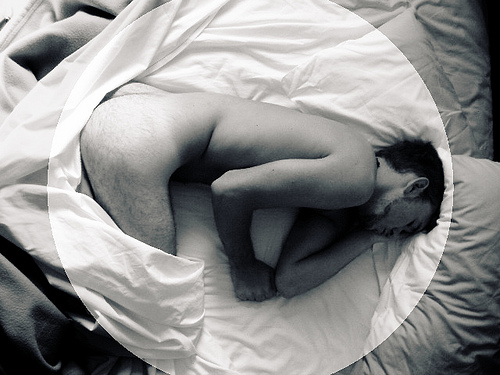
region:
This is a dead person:
[58, 53, 485, 337]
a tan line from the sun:
[131, 92, 191, 167]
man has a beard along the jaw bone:
[360, 193, 403, 235]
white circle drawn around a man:
[48, 5, 453, 371]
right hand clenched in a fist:
[228, 252, 278, 304]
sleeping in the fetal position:
[65, 56, 446, 274]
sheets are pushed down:
[3, 38, 216, 371]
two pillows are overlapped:
[279, 2, 499, 244]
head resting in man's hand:
[355, 136, 442, 264]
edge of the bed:
[472, 3, 497, 155]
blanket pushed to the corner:
[0, 0, 116, 101]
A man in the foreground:
[68, 65, 454, 301]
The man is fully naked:
[56, 62, 447, 306]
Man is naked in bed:
[60, 73, 450, 308]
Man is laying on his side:
[64, 73, 454, 303]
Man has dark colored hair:
[368, 135, 446, 253]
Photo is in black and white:
[3, 2, 497, 374]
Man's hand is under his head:
[272, 185, 397, 313]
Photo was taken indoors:
[6, 5, 496, 373]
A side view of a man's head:
[366, 143, 456, 253]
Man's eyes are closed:
[393, 205, 429, 242]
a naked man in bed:
[78, 76, 446, 334]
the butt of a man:
[79, 73, 186, 186]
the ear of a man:
[402, 172, 430, 199]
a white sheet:
[78, 251, 229, 366]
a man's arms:
[205, 148, 381, 308]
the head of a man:
[369, 136, 453, 243]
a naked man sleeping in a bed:
[63, 75, 465, 310]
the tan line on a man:
[141, 83, 196, 179]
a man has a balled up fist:
[226, 260, 278, 304]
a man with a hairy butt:
[79, 99, 178, 186]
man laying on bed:
[186, 94, 465, 268]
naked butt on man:
[86, 92, 186, 182]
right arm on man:
[211, 179, 305, 305]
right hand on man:
[231, 258, 321, 291]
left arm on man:
[269, 243, 379, 328]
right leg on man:
[94, 197, 213, 267]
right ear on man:
[404, 175, 434, 200]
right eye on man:
[404, 208, 422, 228]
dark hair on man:
[391, 145, 469, 200]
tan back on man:
[219, 96, 349, 173]